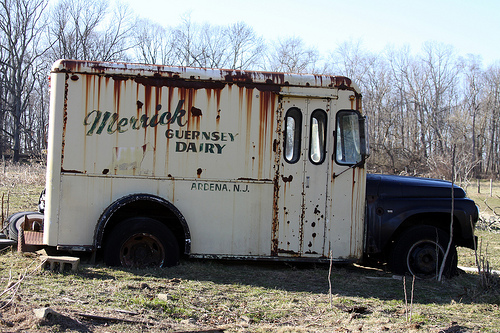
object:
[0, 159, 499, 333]
grass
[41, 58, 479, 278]
truck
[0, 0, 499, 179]
trees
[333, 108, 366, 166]
mirror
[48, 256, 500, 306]
shadow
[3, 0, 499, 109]
sky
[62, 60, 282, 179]
rust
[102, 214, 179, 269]
tires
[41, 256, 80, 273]
block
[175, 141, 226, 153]
dairy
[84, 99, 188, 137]
merrick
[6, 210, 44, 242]
tire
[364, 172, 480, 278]
front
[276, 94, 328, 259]
door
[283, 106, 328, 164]
windows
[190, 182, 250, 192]
ardenna, n.j.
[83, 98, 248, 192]
letters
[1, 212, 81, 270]
junk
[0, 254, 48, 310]
stick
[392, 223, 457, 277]
tire